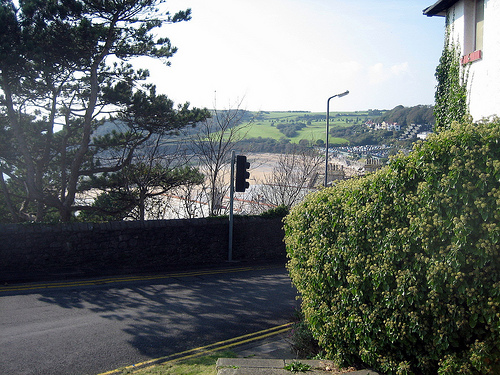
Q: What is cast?
A: Shadow.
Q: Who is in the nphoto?
A: No one.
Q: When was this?
A: Daytime.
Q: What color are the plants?
A: Green.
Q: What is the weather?
A: Sunny.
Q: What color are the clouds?
A: Grey.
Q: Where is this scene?
A: A road.